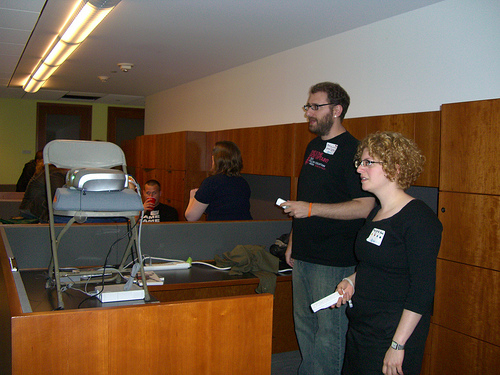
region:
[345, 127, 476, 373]
a woman dressed in black clothing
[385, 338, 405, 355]
wrist watch on woman's left hand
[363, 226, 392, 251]
woman has a name tag on her vest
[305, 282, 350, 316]
woman has wii controller in her hand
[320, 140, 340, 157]
man has name tag on his vest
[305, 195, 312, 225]
man has on orange wrist band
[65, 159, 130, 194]
a video projector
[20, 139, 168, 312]
a folding chair is on top of a desk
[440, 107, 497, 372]
wooden cabinets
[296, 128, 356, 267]
man has on black t-shirt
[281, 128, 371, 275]
the shirt is black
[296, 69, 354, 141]
the man wears glasses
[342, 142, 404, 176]
the woman wears glasses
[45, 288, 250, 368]
the wall is brown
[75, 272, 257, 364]
the wall is wooden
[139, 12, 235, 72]
the ceiling is white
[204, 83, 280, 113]
the wall is white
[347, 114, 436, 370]
the woman is standing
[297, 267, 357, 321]
the controller is white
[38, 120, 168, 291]
the chair is gray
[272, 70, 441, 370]
two people holding game controls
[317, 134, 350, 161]
tag on man's shirt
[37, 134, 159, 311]
folding chair on table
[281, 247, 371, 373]
blue jeans on standing man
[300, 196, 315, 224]
orange bracelet on man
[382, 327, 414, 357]
watch on woman's wrist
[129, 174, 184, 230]
man drinking from cup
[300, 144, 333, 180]
words on man's shirt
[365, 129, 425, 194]
light brown curly hair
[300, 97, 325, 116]
glasses on man's face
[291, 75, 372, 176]
the man is wearing glasses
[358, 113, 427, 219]
the lady is wearing glasses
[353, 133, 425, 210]
the lady has very curly hair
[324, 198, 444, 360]
the lady is wearing a black dress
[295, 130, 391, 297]
the man is wearing an orange armband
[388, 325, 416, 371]
the lady is wearing a watch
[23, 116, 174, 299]
the chair is grey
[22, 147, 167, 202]
the chair has some kind of machine on it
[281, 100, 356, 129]
the man is wearing an earring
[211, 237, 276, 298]
there is a green garment laying on the ledge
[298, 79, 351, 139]
a man wearing glasses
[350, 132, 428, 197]
a lady wearing glasses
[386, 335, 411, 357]
a lady with a watch on her left wrist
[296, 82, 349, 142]
the man has a full beard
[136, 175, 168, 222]
the man is drinking a beverage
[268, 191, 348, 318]
two gamers with controls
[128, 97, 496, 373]
wooden cabinets on the back wall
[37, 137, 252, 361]
a chair on a desk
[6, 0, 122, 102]
a fluorescent light fixture on the ceiling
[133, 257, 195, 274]
an electrical surge protector on the desk